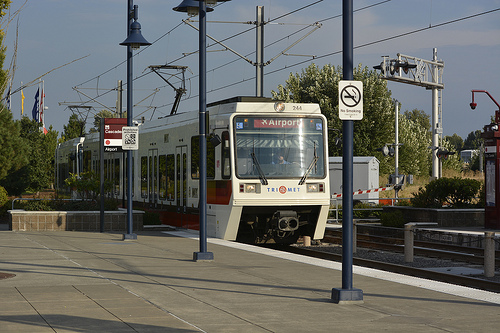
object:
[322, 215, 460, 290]
tracks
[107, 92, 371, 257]
train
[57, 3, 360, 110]
cord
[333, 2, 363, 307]
pole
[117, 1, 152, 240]
pole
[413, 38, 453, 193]
pole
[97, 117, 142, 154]
sign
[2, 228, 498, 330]
pavement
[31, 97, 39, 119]
flag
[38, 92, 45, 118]
flag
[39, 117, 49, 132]
pole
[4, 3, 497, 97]
sky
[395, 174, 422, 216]
ground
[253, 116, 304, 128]
marque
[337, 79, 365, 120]
sign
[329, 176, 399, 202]
gate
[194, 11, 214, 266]
pole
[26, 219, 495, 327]
platform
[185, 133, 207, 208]
doors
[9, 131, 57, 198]
leaves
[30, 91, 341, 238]
train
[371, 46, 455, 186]
light post